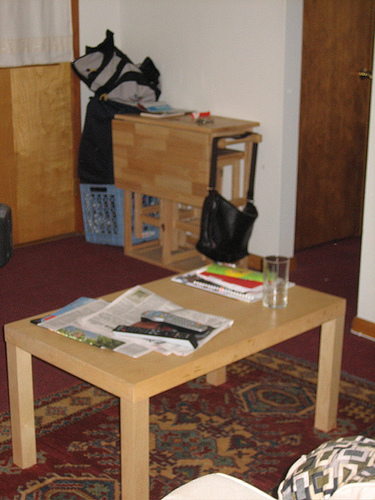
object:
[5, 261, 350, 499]
table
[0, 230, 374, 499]
carpet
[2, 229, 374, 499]
floor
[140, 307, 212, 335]
remote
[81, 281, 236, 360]
newspaper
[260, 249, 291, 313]
glass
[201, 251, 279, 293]
books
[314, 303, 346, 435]
leg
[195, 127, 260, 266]
purse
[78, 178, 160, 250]
basket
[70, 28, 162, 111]
bag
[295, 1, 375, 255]
door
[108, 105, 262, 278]
table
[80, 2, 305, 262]
wall